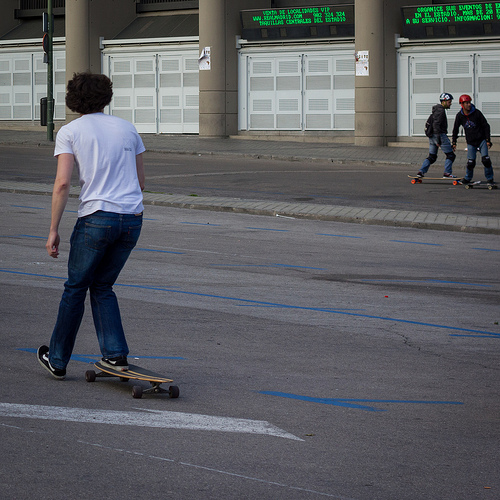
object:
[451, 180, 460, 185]
wheel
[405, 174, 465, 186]
skateboard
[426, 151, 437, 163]
pads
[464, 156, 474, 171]
pads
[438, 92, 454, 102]
helmet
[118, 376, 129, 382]
wheel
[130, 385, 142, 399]
wheel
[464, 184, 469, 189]
wheel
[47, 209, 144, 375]
jeans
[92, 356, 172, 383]
board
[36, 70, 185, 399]
skateboarding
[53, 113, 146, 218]
white shirt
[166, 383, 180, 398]
wheels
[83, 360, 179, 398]
skateboard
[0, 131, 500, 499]
street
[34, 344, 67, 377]
shoes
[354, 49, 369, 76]
flyer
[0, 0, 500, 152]
building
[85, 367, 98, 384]
wheel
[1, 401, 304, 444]
arrow/street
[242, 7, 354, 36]
board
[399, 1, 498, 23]
board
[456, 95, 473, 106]
helmet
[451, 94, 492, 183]
skateboarder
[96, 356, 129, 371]
shoe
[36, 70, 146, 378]
guy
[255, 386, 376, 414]
lines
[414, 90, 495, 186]
they